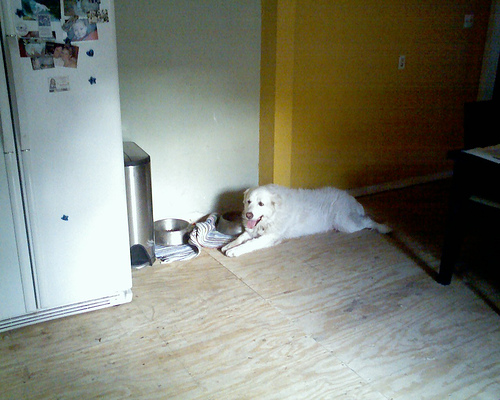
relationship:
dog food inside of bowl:
[146, 211, 215, 256] [163, 229, 182, 244]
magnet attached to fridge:
[85, 70, 100, 90] [9, 24, 116, 275]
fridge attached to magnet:
[9, 24, 116, 275] [85, 70, 100, 90]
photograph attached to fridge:
[22, 39, 84, 65] [9, 24, 116, 275]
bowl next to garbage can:
[163, 229, 182, 244] [125, 150, 158, 250]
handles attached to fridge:
[0, 96, 44, 205] [9, 24, 116, 275]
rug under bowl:
[162, 247, 201, 275] [163, 229, 182, 244]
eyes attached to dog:
[244, 201, 266, 211] [221, 183, 408, 250]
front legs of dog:
[224, 238, 273, 259] [221, 183, 408, 250]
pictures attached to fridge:
[4, 1, 99, 83] [9, 24, 116, 275]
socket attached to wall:
[389, 48, 424, 74] [299, 0, 355, 112]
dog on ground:
[221, 183, 408, 250] [217, 292, 309, 343]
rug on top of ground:
[162, 247, 201, 275] [217, 292, 309, 343]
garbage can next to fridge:
[125, 150, 158, 250] [9, 24, 116, 275]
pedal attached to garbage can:
[124, 240, 153, 264] [125, 150, 158, 250]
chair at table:
[452, 94, 497, 136] [460, 138, 496, 169]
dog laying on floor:
[221, 183, 408, 250] [238, 280, 315, 302]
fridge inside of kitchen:
[9, 24, 116, 275] [50, 1, 335, 323]